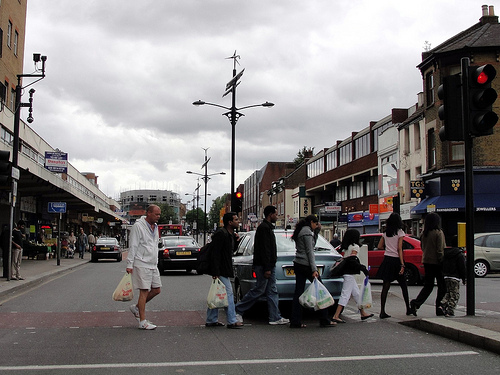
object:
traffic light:
[429, 58, 496, 148]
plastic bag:
[198, 275, 236, 309]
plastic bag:
[282, 267, 334, 308]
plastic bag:
[356, 275, 383, 311]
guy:
[116, 194, 174, 329]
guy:
[192, 204, 250, 319]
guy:
[235, 205, 290, 326]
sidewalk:
[409, 313, 496, 363]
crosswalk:
[0, 300, 390, 374]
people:
[408, 212, 445, 320]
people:
[380, 216, 418, 318]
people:
[335, 227, 372, 328]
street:
[2, 260, 110, 373]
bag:
[110, 272, 136, 301]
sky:
[25, 1, 187, 115]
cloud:
[73, 2, 381, 61]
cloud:
[233, 121, 322, 146]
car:
[233, 221, 358, 326]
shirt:
[119, 215, 166, 273]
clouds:
[148, 107, 190, 147]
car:
[90, 236, 124, 263]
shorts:
[129, 262, 162, 292]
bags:
[313, 276, 335, 312]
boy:
[204, 209, 253, 331]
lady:
[287, 214, 338, 330]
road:
[0, 259, 494, 370]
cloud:
[275, 20, 368, 134]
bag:
[195, 232, 228, 275]